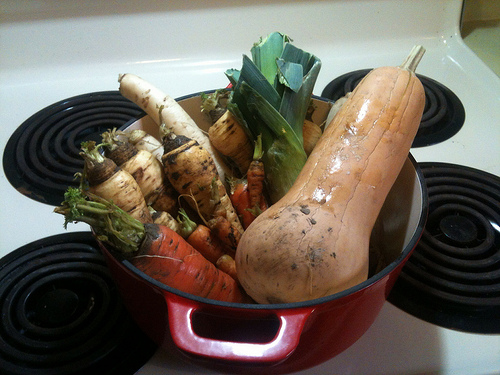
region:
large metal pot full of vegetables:
[58, 28, 453, 368]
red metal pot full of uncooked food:
[59, 30, 444, 372]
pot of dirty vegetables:
[52, 19, 452, 369]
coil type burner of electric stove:
[377, 152, 497, 334]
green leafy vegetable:
[224, 29, 331, 214]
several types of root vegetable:
[68, 99, 257, 307]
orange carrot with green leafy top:
[68, 191, 260, 322]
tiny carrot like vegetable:
[237, 131, 272, 217]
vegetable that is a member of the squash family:
[229, 40, 439, 317]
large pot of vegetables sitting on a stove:
[1, 8, 484, 372]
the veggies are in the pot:
[52, 20, 439, 374]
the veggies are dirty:
[59, 25, 444, 305]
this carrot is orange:
[50, 184, 251, 311]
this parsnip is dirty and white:
[72, 138, 150, 230]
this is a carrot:
[50, 185, 250, 320]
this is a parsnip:
[76, 146, 156, 231]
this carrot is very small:
[241, 130, 269, 228]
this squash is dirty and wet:
[230, 40, 437, 315]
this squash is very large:
[231, 39, 438, 313]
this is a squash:
[230, 40, 440, 309]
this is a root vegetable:
[66, 192, 248, 308]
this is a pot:
[82, 84, 439, 374]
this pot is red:
[89, 78, 422, 373]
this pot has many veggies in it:
[71, 24, 441, 374]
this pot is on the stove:
[81, 78, 436, 370]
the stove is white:
[1, 2, 498, 374]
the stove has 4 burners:
[1, 58, 496, 374]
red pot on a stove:
[82, 87, 427, 371]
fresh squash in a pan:
[235, 41, 432, 303]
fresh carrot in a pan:
[52, 179, 241, 314]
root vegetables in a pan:
[60, 64, 261, 304]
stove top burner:
[377, 161, 497, 331]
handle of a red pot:
[168, 291, 313, 364]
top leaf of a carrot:
[56, 181, 145, 259]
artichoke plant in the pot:
[221, 32, 318, 204]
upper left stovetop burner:
[5, 87, 147, 208]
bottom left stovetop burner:
[0, 227, 172, 372]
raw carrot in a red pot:
[140, 216, 242, 298]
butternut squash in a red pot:
[243, 50, 434, 310]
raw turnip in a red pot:
[157, 126, 238, 214]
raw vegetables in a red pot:
[70, 68, 440, 336]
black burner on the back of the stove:
[4, 76, 150, 214]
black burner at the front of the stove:
[7, 225, 172, 371]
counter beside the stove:
[463, 2, 498, 47]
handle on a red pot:
[161, 282, 309, 362]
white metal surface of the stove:
[379, 319, 424, 374]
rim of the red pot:
[408, 158, 430, 235]